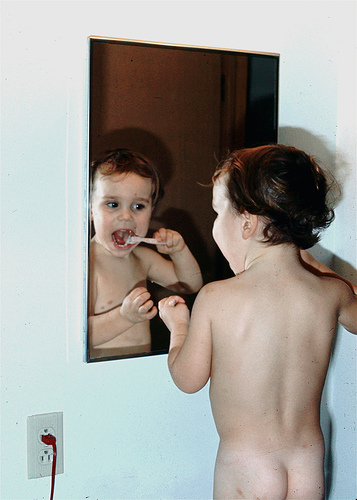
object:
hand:
[157, 293, 188, 329]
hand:
[120, 285, 157, 321]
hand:
[153, 226, 186, 254]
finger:
[159, 226, 166, 242]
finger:
[166, 228, 172, 247]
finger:
[172, 233, 179, 247]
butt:
[212, 441, 325, 498]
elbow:
[168, 368, 212, 394]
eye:
[105, 201, 119, 209]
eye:
[134, 203, 144, 210]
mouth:
[110, 226, 138, 249]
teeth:
[112, 231, 132, 246]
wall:
[0, 0, 325, 500]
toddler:
[88, 146, 203, 362]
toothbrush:
[124, 235, 167, 245]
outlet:
[27, 409, 64, 481]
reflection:
[88, 147, 204, 360]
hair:
[213, 145, 338, 243]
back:
[208, 265, 341, 447]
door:
[90, 42, 247, 355]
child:
[157, 142, 357, 500]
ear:
[240, 207, 258, 239]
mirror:
[84, 37, 277, 365]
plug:
[40, 431, 58, 500]